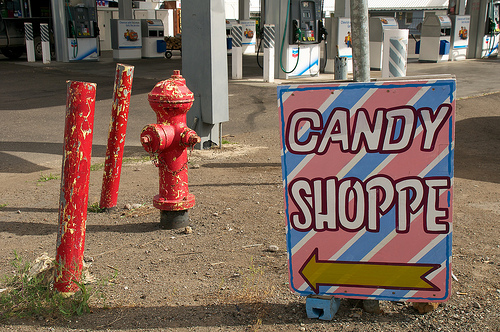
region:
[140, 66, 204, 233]
Faded red fire hydrant on a black post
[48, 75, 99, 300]
Faded red pole in the ground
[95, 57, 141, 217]
Faded red pole in the ground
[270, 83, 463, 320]
Pink, blue, and white sign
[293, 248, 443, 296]
Yellow arrow with brown outlining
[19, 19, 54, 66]
Two white poles with black and white striped tops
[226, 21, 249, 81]
White pole with striped top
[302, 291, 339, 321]
Blue brick underneath the decorative sign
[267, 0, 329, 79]
White and black gas pump with colorful designs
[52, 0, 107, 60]
White and black gas pump with colorful designs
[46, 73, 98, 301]
The pole is red.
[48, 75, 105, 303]
The paint on the pole is chipped.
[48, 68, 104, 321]
The pole is metal.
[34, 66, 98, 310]
The pole is stuck in the ground.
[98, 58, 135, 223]
The pole is red.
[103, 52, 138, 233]
The pole has chipped paint.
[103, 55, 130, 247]
The pole is metal.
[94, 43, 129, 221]
The pole is stuck in the ground.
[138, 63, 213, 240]
The fire hydrant is red.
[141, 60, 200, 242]
The paint on the hydrant is chipped.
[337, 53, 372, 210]
pink and blue sign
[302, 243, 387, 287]
tan arrow on sign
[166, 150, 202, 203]
red fire hydrant behind sign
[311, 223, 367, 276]
white stripes on sign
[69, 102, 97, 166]
red weathered safety pole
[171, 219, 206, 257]
rocks and pebbles on ground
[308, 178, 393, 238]
white letters on sign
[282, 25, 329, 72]
gas pump in the background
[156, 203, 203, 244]
black base hydrant is on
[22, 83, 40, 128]
shadow on ground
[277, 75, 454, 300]
Pink, white, and light blue sign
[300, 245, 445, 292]
Green arrow on sign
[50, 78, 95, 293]
Red pole on ground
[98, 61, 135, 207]
Red pole on ground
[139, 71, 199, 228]
Red fire hydrant on ground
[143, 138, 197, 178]
Red chain on red fire hydrant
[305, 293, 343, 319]
Blue brick on sign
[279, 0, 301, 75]
Green gas pump at gas station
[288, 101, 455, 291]
Pink stripe on sign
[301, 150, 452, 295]
Blue stripe on sign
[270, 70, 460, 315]
the sign is pink white and blue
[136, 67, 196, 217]
the fire hydrant is red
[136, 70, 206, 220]
paint scratched off hydrant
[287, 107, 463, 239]
white letters on sign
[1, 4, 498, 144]
gas station in background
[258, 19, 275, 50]
the pole is striped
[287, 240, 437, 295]
the arrow is yellow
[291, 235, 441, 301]
arrow is pointing left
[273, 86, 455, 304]
the sign is striped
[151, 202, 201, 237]
base of hydrant is black